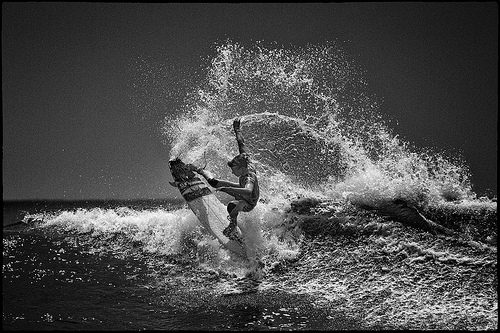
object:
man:
[216, 138, 266, 240]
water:
[42, 226, 190, 328]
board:
[167, 154, 228, 250]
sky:
[6, 3, 161, 80]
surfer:
[195, 116, 262, 240]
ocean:
[3, 202, 496, 330]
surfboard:
[166, 157, 248, 263]